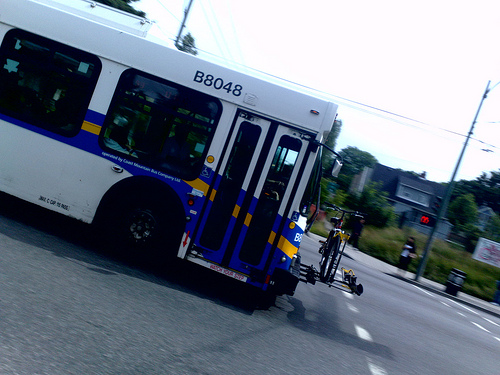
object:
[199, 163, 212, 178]
sign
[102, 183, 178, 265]
wheel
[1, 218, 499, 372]
street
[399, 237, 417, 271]
pedestrian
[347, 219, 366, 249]
person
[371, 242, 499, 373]
crosswalk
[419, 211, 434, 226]
crosswalk signal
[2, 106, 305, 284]
stripe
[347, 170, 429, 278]
corner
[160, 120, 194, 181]
person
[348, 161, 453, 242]
house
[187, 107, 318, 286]
door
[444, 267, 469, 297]
box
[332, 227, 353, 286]
rack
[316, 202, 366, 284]
bicycle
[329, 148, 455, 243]
buildings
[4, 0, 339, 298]
bus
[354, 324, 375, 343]
lines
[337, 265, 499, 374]
cross walk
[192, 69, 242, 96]
id number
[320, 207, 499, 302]
grass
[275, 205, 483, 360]
pavement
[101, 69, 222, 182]
window